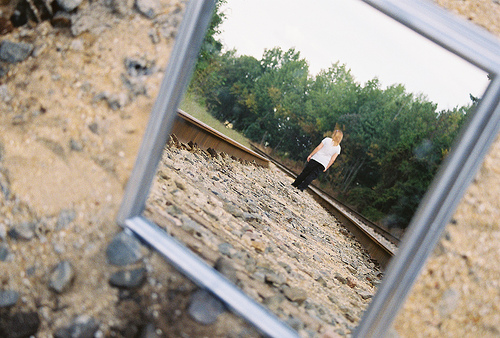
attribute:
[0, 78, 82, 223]
ground — rocky, dirty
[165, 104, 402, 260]
tracks — reflected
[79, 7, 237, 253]
frame — grey, silver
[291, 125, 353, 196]
woman — reflected, standing, facing away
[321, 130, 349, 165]
shirt — white, short-sleeve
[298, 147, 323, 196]
pants — black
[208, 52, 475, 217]
trees — reflected, in reflection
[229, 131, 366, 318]
rocks — grey, small;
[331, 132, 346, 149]
hair — blonde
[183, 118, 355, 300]
ties — wooden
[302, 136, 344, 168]
arms — at sides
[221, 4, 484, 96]
sky — grey